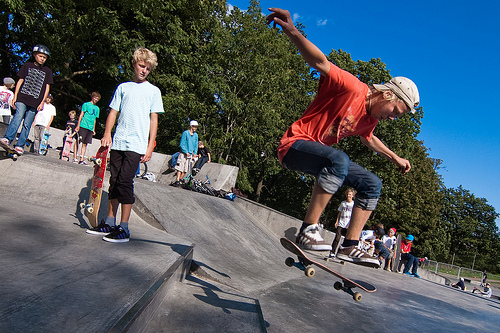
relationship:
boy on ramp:
[61, 107, 80, 161] [137, 179, 301, 292]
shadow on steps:
[140, 235, 261, 316] [118, 237, 269, 331]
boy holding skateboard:
[91, 32, 162, 251] [73, 137, 110, 235]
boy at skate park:
[266, 8, 421, 268] [11, 147, 494, 331]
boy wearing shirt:
[266, 8, 421, 268] [309, 61, 391, 149]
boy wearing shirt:
[266, 8, 421, 268] [277, 61, 379, 164]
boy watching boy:
[266, 8, 421, 268] [72, 43, 169, 250]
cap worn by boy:
[372, 76, 420, 114] [266, 8, 421, 268]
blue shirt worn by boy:
[109, 81, 165, 155] [85, 50, 164, 243]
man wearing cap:
[400, 231, 427, 276] [405, 231, 420, 243]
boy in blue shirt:
[85, 50, 164, 243] [110, 84, 165, 149]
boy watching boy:
[85, 50, 164, 243] [266, 8, 421, 268]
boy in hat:
[85, 50, 164, 243] [1, 72, 17, 83]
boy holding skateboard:
[75, 91, 100, 163] [59, 135, 72, 162]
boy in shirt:
[75, 91, 100, 163] [80, 101, 99, 131]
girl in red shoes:
[11, 35, 60, 160] [2, 133, 22, 158]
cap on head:
[368, 70, 428, 116] [364, 62, 424, 128]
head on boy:
[364, 62, 424, 128] [266, 1, 419, 275]